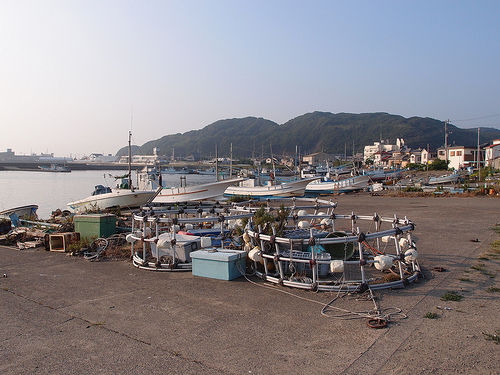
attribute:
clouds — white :
[73, 36, 140, 89]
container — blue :
[188, 245, 248, 284]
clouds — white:
[90, 53, 109, 68]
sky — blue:
[2, 2, 497, 165]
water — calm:
[19, 167, 97, 202]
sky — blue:
[350, 26, 463, 100]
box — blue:
[173, 226, 258, 296]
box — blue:
[188, 247, 248, 283]